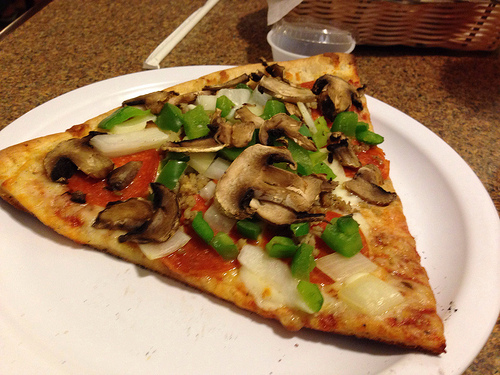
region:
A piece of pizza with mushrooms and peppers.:
[2, 45, 466, 362]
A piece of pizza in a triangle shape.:
[6, 32, 461, 365]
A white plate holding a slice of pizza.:
[4, 37, 486, 373]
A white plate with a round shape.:
[2, 56, 491, 361]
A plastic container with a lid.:
[257, 10, 373, 76]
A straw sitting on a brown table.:
[131, 4, 241, 68]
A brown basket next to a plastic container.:
[255, 1, 480, 77]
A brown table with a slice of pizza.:
[5, 8, 490, 368]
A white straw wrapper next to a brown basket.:
[97, 7, 282, 70]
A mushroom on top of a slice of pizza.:
[202, 134, 326, 238]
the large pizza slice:
[12, 52, 443, 350]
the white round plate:
[19, 57, 499, 369]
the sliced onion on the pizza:
[328, 256, 396, 318]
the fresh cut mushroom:
[220, 142, 312, 214]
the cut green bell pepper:
[193, 205, 371, 273]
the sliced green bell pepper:
[202, 207, 364, 279]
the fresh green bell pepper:
[190, 206, 366, 276]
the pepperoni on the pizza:
[155, 210, 258, 272]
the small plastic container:
[257, 14, 350, 66]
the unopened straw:
[125, 0, 242, 66]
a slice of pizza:
[73, 92, 439, 350]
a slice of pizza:
[144, 160, 369, 371]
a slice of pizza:
[151, 52, 301, 267]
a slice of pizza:
[129, 6, 344, 346]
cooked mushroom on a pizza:
[205, 141, 310, 224]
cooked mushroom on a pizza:
[90, 178, 180, 252]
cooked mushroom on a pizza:
[41, 129, 111, 186]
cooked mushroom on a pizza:
[309, 73, 364, 113]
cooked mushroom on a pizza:
[340, 166, 402, 211]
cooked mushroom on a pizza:
[256, 109, 319, 157]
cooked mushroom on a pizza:
[159, 109, 253, 164]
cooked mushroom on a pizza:
[252, 66, 315, 107]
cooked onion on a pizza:
[337, 258, 404, 325]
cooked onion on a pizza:
[309, 242, 375, 283]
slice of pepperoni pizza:
[3, 50, 445, 353]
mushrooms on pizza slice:
[216, 112, 331, 226]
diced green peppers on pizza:
[155, 101, 210, 183]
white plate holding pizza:
[5, 63, 499, 373]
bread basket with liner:
[278, 3, 499, 52]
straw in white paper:
[138, 0, 216, 65]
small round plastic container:
[267, 22, 358, 60]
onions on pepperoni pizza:
[314, 245, 403, 321]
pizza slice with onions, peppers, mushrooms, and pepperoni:
[7, 51, 446, 356]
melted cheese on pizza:
[33, 188, 90, 245]